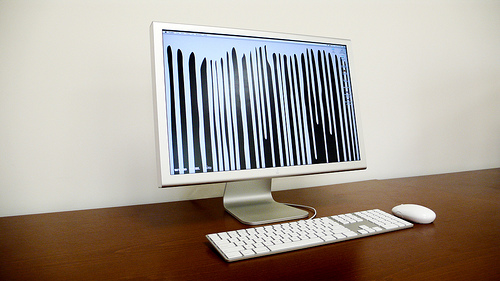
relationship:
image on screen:
[163, 34, 361, 174] [149, 20, 366, 187]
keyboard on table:
[205, 209, 414, 262] [0, 167, 499, 280]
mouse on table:
[392, 203, 437, 224] [0, 167, 499, 280]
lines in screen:
[167, 45, 358, 175] [149, 20, 366, 187]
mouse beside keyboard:
[392, 203, 437, 224] [205, 209, 414, 262]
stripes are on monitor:
[167, 45, 358, 175] [149, 20, 366, 187]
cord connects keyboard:
[282, 203, 317, 220] [205, 209, 414, 262]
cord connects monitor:
[282, 203, 317, 220] [149, 20, 366, 187]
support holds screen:
[223, 178, 310, 225] [149, 20, 366, 187]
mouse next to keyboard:
[392, 203, 437, 224] [205, 209, 414, 262]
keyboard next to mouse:
[205, 209, 414, 262] [392, 203, 437, 224]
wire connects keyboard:
[282, 203, 317, 220] [205, 209, 414, 262]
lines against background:
[167, 45, 358, 175] [163, 34, 361, 174]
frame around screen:
[149, 20, 366, 187] [149, 20, 366, 187]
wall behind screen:
[1, 0, 500, 218] [149, 20, 366, 187]